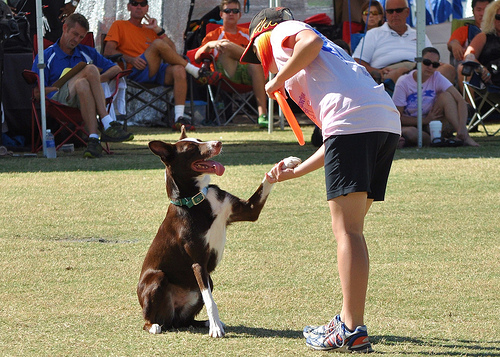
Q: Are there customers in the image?
A: No, there are no customers.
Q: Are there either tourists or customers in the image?
A: No, there are no customers or tourists.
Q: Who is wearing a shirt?
A: The man is wearing a shirt.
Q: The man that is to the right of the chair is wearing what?
A: The man is wearing a shirt.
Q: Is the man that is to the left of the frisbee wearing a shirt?
A: Yes, the man is wearing a shirt.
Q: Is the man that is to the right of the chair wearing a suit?
A: No, the man is wearing a shirt.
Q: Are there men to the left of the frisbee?
A: Yes, there is a man to the left of the frisbee.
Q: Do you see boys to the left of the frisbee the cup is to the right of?
A: No, there is a man to the left of the frisbee.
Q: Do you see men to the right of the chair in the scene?
A: Yes, there is a man to the right of the chair.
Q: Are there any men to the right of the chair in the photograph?
A: Yes, there is a man to the right of the chair.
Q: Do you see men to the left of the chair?
A: No, the man is to the right of the chair.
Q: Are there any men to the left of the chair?
A: No, the man is to the right of the chair.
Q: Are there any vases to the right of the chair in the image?
A: No, there is a man to the right of the chair.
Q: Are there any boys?
A: No, there are no boys.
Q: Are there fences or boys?
A: No, there are no boys or fences.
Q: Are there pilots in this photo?
A: No, there are no pilots.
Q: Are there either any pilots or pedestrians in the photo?
A: No, there are no pilots or pedestrians.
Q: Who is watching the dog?
A: The spectators are watching the dog.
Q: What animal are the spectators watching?
A: The spectators are watching the dog.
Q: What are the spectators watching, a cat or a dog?
A: The spectators are watching a dog.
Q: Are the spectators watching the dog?
A: Yes, the spectators are watching the dog.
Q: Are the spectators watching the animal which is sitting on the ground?
A: Yes, the spectators are watching the dog.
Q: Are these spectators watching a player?
A: No, the spectators are watching the dog.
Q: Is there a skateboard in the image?
A: No, there are no skateboards.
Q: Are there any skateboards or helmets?
A: No, there are no skateboards or helmets.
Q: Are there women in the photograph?
A: Yes, there is a woman.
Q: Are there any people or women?
A: Yes, there is a woman.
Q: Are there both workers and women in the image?
A: No, there is a woman but no workers.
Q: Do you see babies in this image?
A: No, there are no babies.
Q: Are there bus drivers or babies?
A: No, there are no babies or bus drivers.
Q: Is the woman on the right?
A: Yes, the woman is on the right of the image.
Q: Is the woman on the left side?
A: No, the woman is on the right of the image.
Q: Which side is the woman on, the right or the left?
A: The woman is on the right of the image.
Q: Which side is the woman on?
A: The woman is on the right of the image.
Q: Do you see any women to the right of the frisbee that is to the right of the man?
A: Yes, there is a woman to the right of the frisbee.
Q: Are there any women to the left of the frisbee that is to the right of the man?
A: No, the woman is to the right of the frisbee.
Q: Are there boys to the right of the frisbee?
A: No, there is a woman to the right of the frisbee.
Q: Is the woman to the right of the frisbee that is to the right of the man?
A: Yes, the woman is to the right of the frisbee.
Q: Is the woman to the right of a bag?
A: No, the woman is to the right of the frisbee.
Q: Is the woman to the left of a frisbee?
A: No, the woman is to the right of a frisbee.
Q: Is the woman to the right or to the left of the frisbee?
A: The woman is to the right of the frisbee.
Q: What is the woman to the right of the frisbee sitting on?
A: The woman is sitting on the ground.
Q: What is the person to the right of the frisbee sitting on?
A: The woman is sitting on the ground.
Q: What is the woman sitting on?
A: The woman is sitting on the ground.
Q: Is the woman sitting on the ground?
A: Yes, the woman is sitting on the ground.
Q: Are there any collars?
A: Yes, there is a collar.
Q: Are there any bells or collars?
A: Yes, there is a collar.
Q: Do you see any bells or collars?
A: Yes, there is a collar.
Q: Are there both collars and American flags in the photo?
A: No, there is a collar but no American flags.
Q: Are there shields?
A: No, there are no shields.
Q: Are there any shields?
A: No, there are no shields.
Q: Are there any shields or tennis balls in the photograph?
A: No, there are no shields or tennis balls.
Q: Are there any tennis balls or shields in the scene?
A: No, there are no shields or tennis balls.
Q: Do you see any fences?
A: No, there are no fences.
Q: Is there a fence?
A: No, there are no fences.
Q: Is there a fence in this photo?
A: No, there are no fences.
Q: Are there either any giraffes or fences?
A: No, there are no fences or giraffes.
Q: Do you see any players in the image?
A: No, there are no players.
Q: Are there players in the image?
A: No, there are no players.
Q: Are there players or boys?
A: No, there are no players or boys.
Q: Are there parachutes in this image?
A: No, there are no parachutes.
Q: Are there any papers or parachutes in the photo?
A: No, there are no parachutes or papers.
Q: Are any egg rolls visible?
A: No, there are no egg rolls.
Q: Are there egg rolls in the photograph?
A: No, there are no egg rolls.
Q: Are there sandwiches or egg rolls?
A: No, there are no egg rolls or sandwiches.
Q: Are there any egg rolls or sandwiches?
A: No, there are no egg rolls or sandwiches.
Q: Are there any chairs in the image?
A: Yes, there is a chair.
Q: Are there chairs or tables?
A: Yes, there is a chair.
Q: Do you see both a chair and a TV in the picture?
A: No, there is a chair but no televisions.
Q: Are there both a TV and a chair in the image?
A: No, there is a chair but no televisions.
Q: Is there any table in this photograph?
A: No, there are no tables.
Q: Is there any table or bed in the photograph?
A: No, there are no tables or beds.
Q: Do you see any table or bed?
A: No, there are no tables or beds.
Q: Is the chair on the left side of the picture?
A: Yes, the chair is on the left of the image.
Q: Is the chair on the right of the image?
A: No, the chair is on the left of the image.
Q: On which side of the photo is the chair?
A: The chair is on the left of the image.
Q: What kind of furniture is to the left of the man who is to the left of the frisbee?
A: The piece of furniture is a chair.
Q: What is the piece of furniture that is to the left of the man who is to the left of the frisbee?
A: The piece of furniture is a chair.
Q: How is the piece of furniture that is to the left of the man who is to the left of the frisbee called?
A: The piece of furniture is a chair.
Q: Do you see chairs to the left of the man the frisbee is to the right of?
A: Yes, there is a chair to the left of the man.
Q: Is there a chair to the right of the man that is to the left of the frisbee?
A: No, the chair is to the left of the man.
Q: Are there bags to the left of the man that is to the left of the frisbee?
A: No, there is a chair to the left of the man.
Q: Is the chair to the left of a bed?
A: No, the chair is to the left of a man.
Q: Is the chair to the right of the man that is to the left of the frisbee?
A: No, the chair is to the left of the man.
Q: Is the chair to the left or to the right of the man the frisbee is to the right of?
A: The chair is to the left of the man.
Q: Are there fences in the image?
A: No, there are no fences.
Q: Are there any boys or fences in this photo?
A: No, there are no fences or boys.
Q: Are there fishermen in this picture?
A: No, there are no fishermen.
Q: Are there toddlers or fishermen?
A: No, there are no fishermen or toddlers.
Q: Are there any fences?
A: No, there are no fences.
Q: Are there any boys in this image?
A: No, there are no boys.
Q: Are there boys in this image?
A: No, there are no boys.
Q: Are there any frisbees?
A: Yes, there is a frisbee.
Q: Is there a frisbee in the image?
A: Yes, there is a frisbee.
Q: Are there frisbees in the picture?
A: Yes, there is a frisbee.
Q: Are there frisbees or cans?
A: Yes, there is a frisbee.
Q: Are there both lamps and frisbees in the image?
A: No, there is a frisbee but no lamps.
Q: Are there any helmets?
A: No, there are no helmets.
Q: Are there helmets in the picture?
A: No, there are no helmets.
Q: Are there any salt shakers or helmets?
A: No, there are no helmets or salt shakers.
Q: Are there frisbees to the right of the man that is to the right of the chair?
A: Yes, there is a frisbee to the right of the man.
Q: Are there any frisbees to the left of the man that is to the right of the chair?
A: No, the frisbee is to the right of the man.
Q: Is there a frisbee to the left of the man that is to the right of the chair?
A: No, the frisbee is to the right of the man.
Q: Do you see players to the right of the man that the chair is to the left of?
A: No, there is a frisbee to the right of the man.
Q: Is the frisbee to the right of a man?
A: Yes, the frisbee is to the right of a man.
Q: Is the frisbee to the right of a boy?
A: No, the frisbee is to the right of a man.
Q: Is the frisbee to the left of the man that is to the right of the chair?
A: No, the frisbee is to the right of the man.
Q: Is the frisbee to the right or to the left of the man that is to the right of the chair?
A: The frisbee is to the right of the man.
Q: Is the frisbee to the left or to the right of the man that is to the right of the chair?
A: The frisbee is to the right of the man.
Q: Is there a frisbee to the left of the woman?
A: Yes, there is a frisbee to the left of the woman.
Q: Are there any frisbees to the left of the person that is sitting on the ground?
A: Yes, there is a frisbee to the left of the woman.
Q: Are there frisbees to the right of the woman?
A: No, the frisbee is to the left of the woman.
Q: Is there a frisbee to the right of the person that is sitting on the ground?
A: No, the frisbee is to the left of the woman.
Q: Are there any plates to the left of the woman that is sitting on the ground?
A: No, there is a frisbee to the left of the woman.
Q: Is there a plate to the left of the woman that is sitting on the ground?
A: No, there is a frisbee to the left of the woman.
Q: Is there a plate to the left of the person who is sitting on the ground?
A: No, there is a frisbee to the left of the woman.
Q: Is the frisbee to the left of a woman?
A: Yes, the frisbee is to the left of a woman.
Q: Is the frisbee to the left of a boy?
A: No, the frisbee is to the left of a woman.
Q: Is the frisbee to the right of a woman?
A: No, the frisbee is to the left of a woman.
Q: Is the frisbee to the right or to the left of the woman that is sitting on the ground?
A: The frisbee is to the left of the woman.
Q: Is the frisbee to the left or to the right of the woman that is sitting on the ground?
A: The frisbee is to the left of the woman.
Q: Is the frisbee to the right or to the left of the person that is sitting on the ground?
A: The frisbee is to the left of the woman.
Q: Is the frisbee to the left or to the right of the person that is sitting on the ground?
A: The frisbee is to the left of the woman.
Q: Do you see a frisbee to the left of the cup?
A: Yes, there is a frisbee to the left of the cup.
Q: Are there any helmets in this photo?
A: No, there are no helmets.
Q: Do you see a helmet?
A: No, there are no helmets.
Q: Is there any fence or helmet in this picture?
A: No, there are no helmets or fences.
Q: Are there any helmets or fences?
A: No, there are no helmets or fences.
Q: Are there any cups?
A: Yes, there is a cup.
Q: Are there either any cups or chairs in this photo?
A: Yes, there is a cup.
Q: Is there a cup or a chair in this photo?
A: Yes, there is a cup.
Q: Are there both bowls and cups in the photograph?
A: No, there is a cup but no bowls.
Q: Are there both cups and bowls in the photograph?
A: No, there is a cup but no bowls.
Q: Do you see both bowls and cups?
A: No, there is a cup but no bowls.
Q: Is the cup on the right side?
A: Yes, the cup is on the right of the image.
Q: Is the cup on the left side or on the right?
A: The cup is on the right of the image.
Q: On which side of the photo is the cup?
A: The cup is on the right of the image.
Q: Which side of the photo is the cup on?
A: The cup is on the right of the image.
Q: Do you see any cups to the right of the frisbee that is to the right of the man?
A: Yes, there is a cup to the right of the frisbee.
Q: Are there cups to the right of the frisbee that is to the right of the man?
A: Yes, there is a cup to the right of the frisbee.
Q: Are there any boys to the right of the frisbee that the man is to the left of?
A: No, there is a cup to the right of the frisbee.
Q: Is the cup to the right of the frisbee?
A: Yes, the cup is to the right of the frisbee.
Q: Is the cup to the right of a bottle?
A: No, the cup is to the right of the frisbee.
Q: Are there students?
A: No, there are no students.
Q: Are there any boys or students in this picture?
A: No, there are no students or boys.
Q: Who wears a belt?
A: The man wears a belt.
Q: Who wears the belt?
A: The man wears a belt.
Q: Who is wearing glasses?
A: The man is wearing glasses.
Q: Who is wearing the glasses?
A: The man is wearing glasses.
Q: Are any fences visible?
A: No, there are no fences.